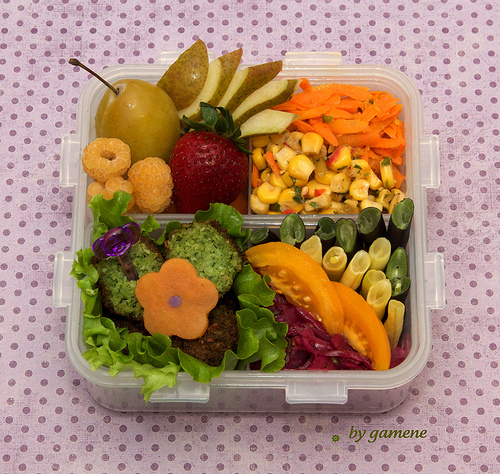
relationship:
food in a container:
[69, 37, 415, 407] [51, 51, 445, 414]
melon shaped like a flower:
[135, 257, 220, 340] [134, 257, 218, 340]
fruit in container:
[68, 40, 298, 214] [51, 51, 445, 414]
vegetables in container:
[70, 78, 415, 405] [51, 51, 445, 414]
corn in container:
[250, 133, 406, 216] [51, 51, 445, 414]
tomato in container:
[245, 240, 391, 371] [51, 51, 445, 414]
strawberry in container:
[168, 101, 253, 215] [51, 51, 445, 414]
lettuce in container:
[70, 189, 289, 402] [51, 51, 445, 414]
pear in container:
[157, 39, 299, 141] [51, 51, 445, 414]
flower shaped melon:
[134, 257, 218, 340] [135, 257, 220, 340]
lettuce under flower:
[70, 189, 289, 402] [134, 257, 218, 340]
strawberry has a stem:
[168, 101, 253, 215] [180, 101, 254, 156]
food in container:
[69, 37, 415, 407] [51, 51, 445, 414]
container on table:
[51, 51, 445, 414] [0, 0, 499, 473]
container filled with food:
[51, 51, 445, 414] [69, 37, 415, 407]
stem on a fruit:
[68, 57, 118, 96] [95, 79, 181, 181]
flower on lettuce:
[134, 257, 218, 340] [70, 189, 289, 402]